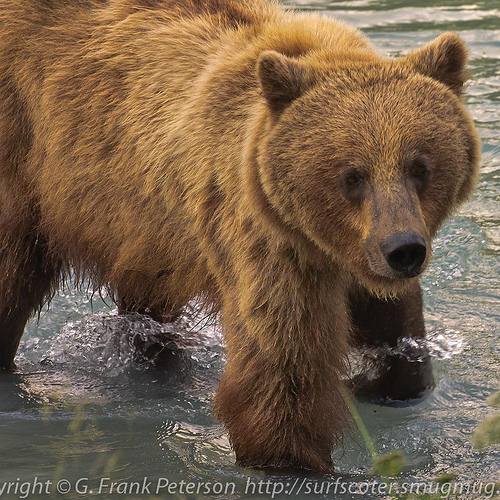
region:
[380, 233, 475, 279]
bear has a black nose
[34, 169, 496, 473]
bear is standing in water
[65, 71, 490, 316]
the bear is brown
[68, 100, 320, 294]
the bear has a lot of hair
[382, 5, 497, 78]
water has a greenish color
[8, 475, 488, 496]
website at the bottom of picture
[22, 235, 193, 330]
bear's hair is wet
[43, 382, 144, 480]
reflection in the water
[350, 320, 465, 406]
the water is splashing on the bear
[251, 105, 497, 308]
bear is looking at the camera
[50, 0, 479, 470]
Big brown bear in water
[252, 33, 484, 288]
Brown bears head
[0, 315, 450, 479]
Legs splashing in the water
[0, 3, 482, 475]
One bear in picture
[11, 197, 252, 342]
Wet belly hair of bear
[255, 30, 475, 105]
Two brown ears of bear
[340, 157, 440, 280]
Eyes and nose of bear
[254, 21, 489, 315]
Bear is looking towards camera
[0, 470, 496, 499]
Writing on bottom of picture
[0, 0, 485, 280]
Top of bear is dry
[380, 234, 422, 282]
bear has a black nose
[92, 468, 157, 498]
White letters that say frank.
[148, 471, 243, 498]
White letters that say peterson.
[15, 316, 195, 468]
A splash of water.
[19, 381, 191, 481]
Green grass under the water.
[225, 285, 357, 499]
Brown furry bear arm.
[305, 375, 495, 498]
Green grass by the water.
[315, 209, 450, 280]
Brown nose of a bear.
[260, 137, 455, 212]
Two brown bear eyes.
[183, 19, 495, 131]
Two brown furry bear ears.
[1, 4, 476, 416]
A brown bear in the water.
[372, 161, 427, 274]
Nose of a brown bear.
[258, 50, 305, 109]
Right ear of a brown bear.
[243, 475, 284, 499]
the letters http in front of a bear.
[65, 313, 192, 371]
Splashes of water on the bear.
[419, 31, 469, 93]
Left ear of a brown bear.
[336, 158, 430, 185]
Eyes on a brown bear standing in the water.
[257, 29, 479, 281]
Head of a brown bear standing in water.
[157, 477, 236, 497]
The last name Peterson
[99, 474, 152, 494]
The name Frank.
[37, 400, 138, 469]
Reflection in the water.